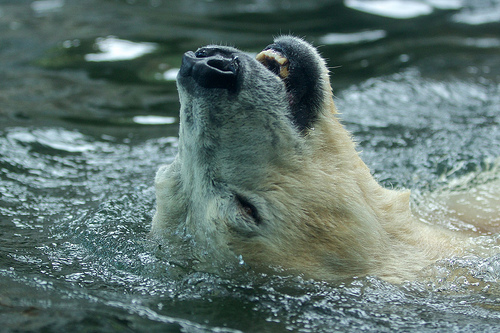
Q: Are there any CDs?
A: No, there are no cds.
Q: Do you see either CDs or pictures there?
A: No, there are no CDs or pictures.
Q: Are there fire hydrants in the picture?
A: No, there are no fire hydrants.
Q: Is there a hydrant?
A: No, there are no fire hydrants.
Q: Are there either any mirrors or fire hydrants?
A: No, there are no fire hydrants or mirrors.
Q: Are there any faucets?
A: No, there are no faucets.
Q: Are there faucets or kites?
A: No, there are no faucets or kites.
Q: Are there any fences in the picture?
A: No, there are no fences.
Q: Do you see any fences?
A: No, there are no fences.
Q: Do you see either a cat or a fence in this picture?
A: No, there are no fences or cats.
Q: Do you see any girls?
A: No, there are no girls.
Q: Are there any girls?
A: No, there are no girls.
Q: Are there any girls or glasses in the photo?
A: No, there are no girls or glasses.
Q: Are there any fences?
A: No, there are no fences.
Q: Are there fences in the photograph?
A: No, there are no fences.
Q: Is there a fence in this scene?
A: No, there are no fences.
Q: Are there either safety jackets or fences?
A: No, there are no fences or safety jackets.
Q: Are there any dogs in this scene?
A: No, there are no dogs.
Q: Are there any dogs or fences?
A: No, there are no dogs or fences.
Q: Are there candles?
A: No, there are no candles.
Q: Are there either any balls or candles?
A: No, there are no candles or balls.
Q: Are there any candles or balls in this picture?
A: No, there are no candles or balls.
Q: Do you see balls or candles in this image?
A: No, there are no candles or balls.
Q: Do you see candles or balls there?
A: No, there are no candles or balls.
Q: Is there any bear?
A: Yes, there is a bear.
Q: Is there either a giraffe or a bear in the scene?
A: Yes, there is a bear.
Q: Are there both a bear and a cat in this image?
A: No, there is a bear but no cats.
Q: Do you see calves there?
A: No, there are no calves.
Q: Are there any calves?
A: No, there are no calves.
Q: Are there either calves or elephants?
A: No, there are no calves or elephants.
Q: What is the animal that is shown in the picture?
A: The animal is a bear.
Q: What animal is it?
A: The animal is a bear.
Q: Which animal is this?
A: This is a bear.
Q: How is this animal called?
A: This is a bear.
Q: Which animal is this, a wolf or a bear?
A: This is a bear.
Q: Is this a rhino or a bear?
A: This is a bear.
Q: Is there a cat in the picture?
A: No, there are no cats.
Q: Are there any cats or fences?
A: No, there are no cats or fences.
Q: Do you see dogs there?
A: No, there are no dogs.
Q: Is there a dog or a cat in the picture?
A: No, there are no dogs or cats.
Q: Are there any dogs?
A: No, there are no dogs.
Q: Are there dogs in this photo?
A: No, there are no dogs.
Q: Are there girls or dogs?
A: No, there are no dogs or girls.